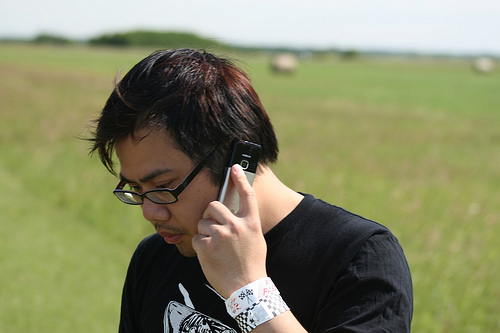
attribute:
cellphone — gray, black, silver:
[213, 140, 265, 214]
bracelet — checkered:
[224, 279, 290, 333]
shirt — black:
[113, 190, 414, 332]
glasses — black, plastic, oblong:
[113, 138, 224, 206]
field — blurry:
[1, 41, 500, 333]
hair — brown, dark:
[92, 49, 280, 184]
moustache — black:
[151, 223, 188, 237]